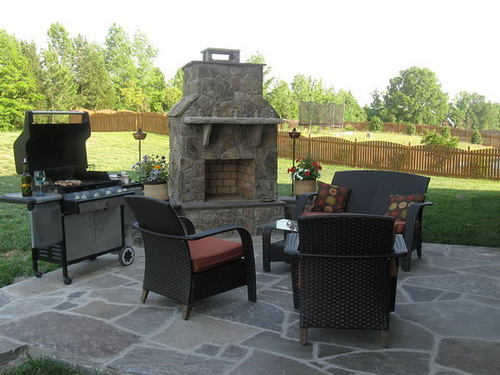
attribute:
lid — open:
[12, 110, 89, 174]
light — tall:
[287, 129, 299, 188]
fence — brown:
[70, 107, 499, 182]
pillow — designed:
[311, 180, 348, 215]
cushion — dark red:
[185, 237, 244, 268]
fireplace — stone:
[170, 54, 274, 205]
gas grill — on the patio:
[6, 105, 144, 285]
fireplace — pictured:
[194, 146, 264, 205]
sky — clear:
[2, 2, 498, 108]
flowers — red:
[285, 156, 325, 180]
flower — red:
[285, 163, 301, 181]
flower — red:
[293, 169, 318, 184]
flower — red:
[307, 160, 326, 176]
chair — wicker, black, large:
[284, 208, 411, 347]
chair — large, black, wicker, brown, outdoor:
[120, 190, 261, 320]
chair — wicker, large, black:
[306, 167, 435, 273]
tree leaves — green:
[416, 90, 437, 114]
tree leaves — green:
[16, 69, 30, 105]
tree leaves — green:
[431, 138, 453, 146]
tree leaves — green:
[155, 77, 169, 103]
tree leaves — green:
[274, 88, 291, 109]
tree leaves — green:
[150, 70, 167, 88]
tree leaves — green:
[2, 91, 22, 119]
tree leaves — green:
[84, 71, 103, 92]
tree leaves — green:
[456, 97, 483, 116]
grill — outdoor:
[5, 105, 143, 285]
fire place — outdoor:
[168, 47, 287, 233]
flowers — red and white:
[286, 153, 321, 180]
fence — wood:
[298, 134, 469, 177]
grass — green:
[99, 133, 128, 156]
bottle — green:
[17, 155, 32, 197]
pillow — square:
[315, 179, 350, 214]